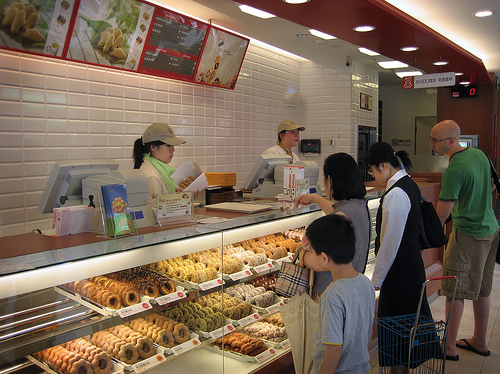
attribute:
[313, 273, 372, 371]
shirt — grey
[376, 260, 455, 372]
cart — small, metal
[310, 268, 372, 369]
shirt — grey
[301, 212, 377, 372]
boy — looking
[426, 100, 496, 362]
man — leaning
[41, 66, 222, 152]
tiles — shiny, white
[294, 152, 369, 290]
woman — pink, blue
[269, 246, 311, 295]
white/pink/blue purse — white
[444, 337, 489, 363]
flip flop — black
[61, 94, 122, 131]
wall — tiled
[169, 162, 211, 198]
box — white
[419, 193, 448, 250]
purse — black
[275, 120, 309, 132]
hat — brown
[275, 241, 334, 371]
umbrella — closed, yellow